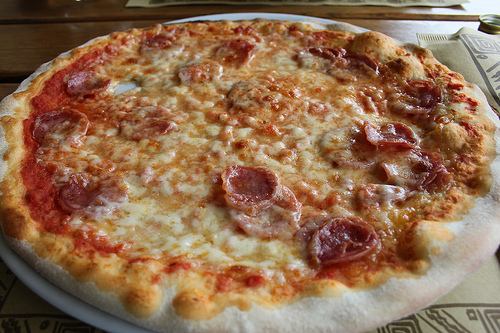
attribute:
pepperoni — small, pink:
[225, 160, 278, 207]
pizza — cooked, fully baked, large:
[1, 18, 500, 332]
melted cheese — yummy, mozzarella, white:
[113, 50, 358, 253]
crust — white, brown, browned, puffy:
[1, 209, 500, 332]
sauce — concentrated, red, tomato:
[21, 47, 99, 246]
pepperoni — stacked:
[222, 160, 301, 246]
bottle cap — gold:
[476, 16, 499, 41]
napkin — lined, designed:
[416, 29, 498, 108]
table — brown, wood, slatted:
[1, 0, 495, 101]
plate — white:
[1, 253, 138, 333]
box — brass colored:
[381, 248, 500, 333]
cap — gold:
[473, 13, 500, 35]